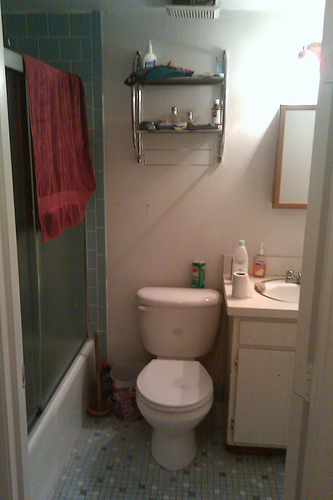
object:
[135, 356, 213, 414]
seat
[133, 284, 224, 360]
toilet tank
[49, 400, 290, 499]
floor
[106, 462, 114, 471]
tiles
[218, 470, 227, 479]
tiles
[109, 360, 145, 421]
trash can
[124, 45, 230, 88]
shelf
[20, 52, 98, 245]
towel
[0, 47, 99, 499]
shower door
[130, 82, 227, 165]
shelves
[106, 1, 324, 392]
wall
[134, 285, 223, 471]
toilet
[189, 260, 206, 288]
comet cleanser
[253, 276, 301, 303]
sink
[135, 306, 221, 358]
porcelain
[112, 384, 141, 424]
waste basket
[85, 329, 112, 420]
plunger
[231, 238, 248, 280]
shampoo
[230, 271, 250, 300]
roll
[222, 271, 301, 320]
counter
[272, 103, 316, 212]
mirror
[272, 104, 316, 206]
frame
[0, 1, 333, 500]
bathroom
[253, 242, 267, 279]
hand soap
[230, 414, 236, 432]
hinge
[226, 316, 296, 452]
cabinetry